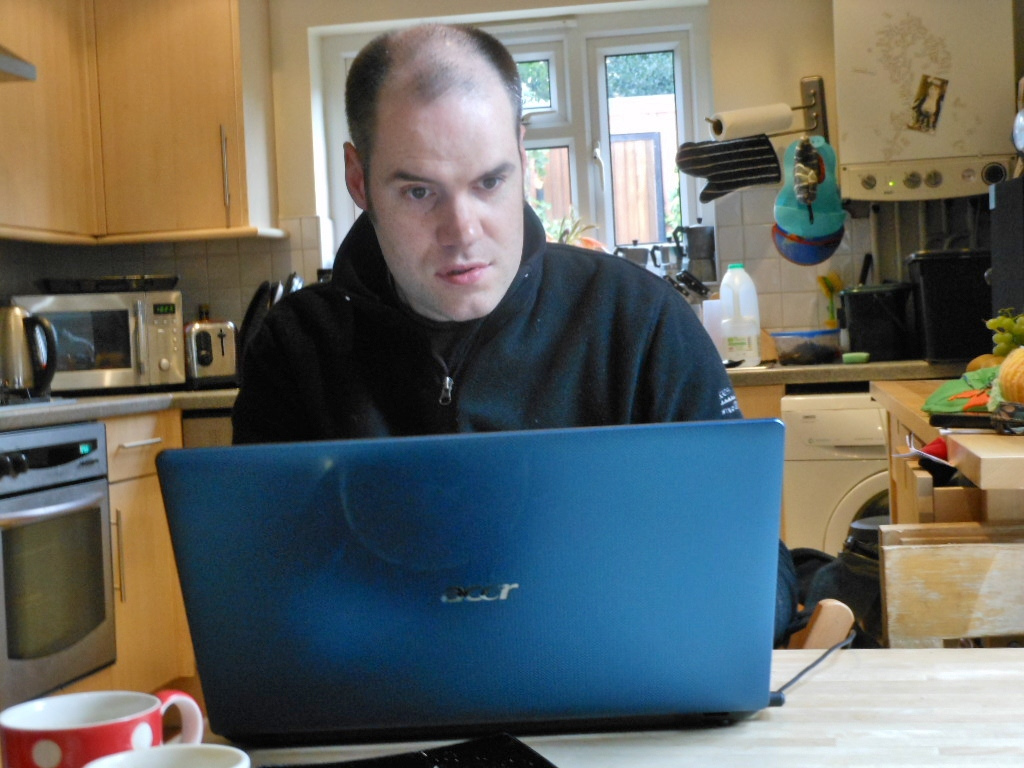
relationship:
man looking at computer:
[227, 11, 744, 441] [153, 392, 795, 732]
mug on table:
[0, 677, 210, 764] [166, 644, 1022, 761]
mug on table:
[80, 733, 249, 764] [166, 644, 1022, 761]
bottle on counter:
[715, 251, 772, 379] [706, 346, 938, 375]